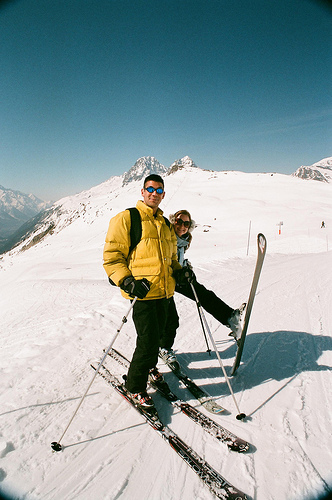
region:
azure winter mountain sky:
[0, 2, 329, 201]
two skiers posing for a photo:
[0, 152, 328, 498]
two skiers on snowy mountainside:
[3, 157, 330, 498]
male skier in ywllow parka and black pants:
[88, 174, 254, 498]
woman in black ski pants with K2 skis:
[168, 209, 267, 416]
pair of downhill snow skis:
[89, 345, 257, 499]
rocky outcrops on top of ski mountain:
[121, 154, 330, 183]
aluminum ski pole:
[51, 296, 137, 452]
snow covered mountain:
[0, 185, 54, 253]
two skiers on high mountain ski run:
[4, 152, 330, 497]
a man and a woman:
[96, 169, 242, 404]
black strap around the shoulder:
[120, 202, 154, 257]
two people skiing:
[41, 160, 286, 498]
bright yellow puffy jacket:
[102, 206, 184, 304]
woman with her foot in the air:
[164, 206, 274, 390]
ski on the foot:
[221, 233, 264, 399]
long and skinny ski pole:
[43, 295, 144, 462]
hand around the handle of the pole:
[121, 274, 154, 304]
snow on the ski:
[210, 422, 237, 447]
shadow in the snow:
[2, 382, 100, 418]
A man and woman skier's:
[47, 162, 272, 496]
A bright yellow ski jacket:
[104, 206, 184, 300]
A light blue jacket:
[176, 236, 191, 277]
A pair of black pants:
[120, 301, 183, 399]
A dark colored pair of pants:
[180, 277, 228, 324]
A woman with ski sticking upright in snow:
[225, 229, 279, 377]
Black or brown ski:
[156, 429, 250, 498]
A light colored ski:
[173, 366, 236, 412]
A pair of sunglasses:
[135, 171, 171, 208]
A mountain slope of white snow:
[10, 153, 330, 347]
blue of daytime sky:
[3, 2, 330, 198]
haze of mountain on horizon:
[0, 186, 54, 245]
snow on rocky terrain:
[22, 155, 331, 244]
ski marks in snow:
[5, 398, 330, 499]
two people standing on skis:
[92, 173, 266, 498]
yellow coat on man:
[103, 173, 175, 298]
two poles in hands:
[51, 268, 244, 452]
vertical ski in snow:
[229, 232, 267, 372]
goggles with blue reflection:
[145, 185, 163, 194]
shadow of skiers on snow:
[167, 329, 328, 407]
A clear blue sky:
[0, 1, 330, 202]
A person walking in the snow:
[319, 219, 325, 229]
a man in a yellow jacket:
[100, 173, 197, 421]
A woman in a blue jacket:
[166, 207, 240, 351]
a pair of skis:
[86, 346, 256, 499]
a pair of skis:
[156, 231, 267, 417]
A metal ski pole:
[49, 278, 146, 453]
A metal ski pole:
[183, 254, 246, 419]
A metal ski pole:
[185, 260, 212, 355]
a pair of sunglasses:
[141, 186, 165, 194]